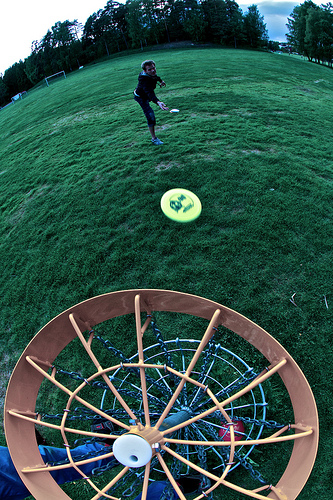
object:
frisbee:
[160, 187, 202, 223]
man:
[133, 59, 167, 146]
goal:
[2, 285, 320, 499]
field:
[0, 51, 333, 485]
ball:
[219, 417, 245, 442]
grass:
[0, 47, 322, 496]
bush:
[85, 1, 270, 52]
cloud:
[252, 1, 300, 43]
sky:
[0, 1, 302, 74]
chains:
[37, 315, 290, 499]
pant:
[0, 441, 112, 497]